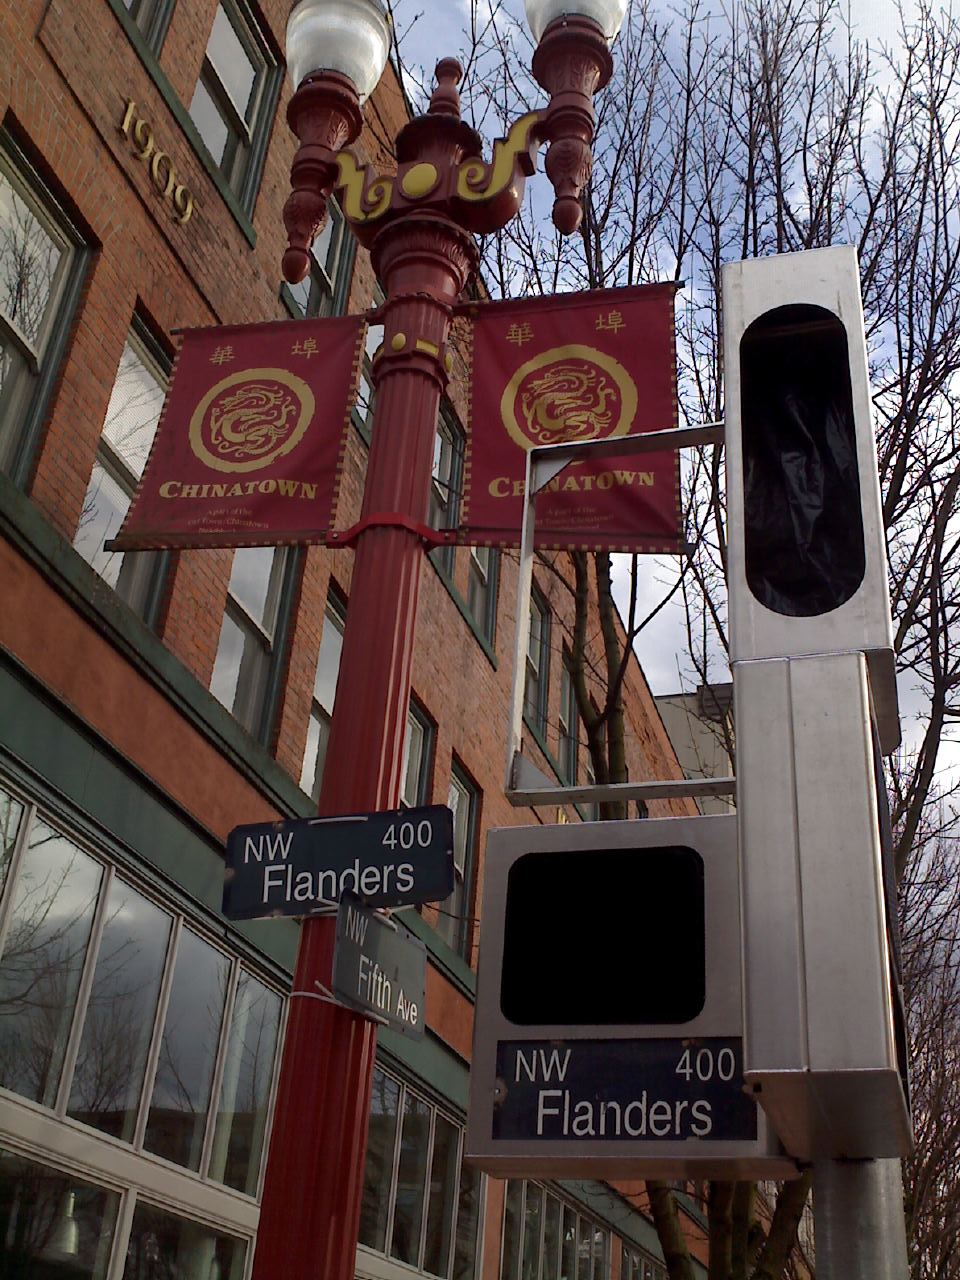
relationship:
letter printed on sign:
[532, 1085, 565, 1135] [486, 1040, 760, 1142]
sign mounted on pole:
[486, 1040, 760, 1142] [804, 1148, 908, 1275]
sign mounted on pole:
[328, 883, 430, 1041] [246, 209, 483, 1277]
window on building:
[72, 437, 145, 597] [2, 7, 749, 1277]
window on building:
[197, 594, 287, 733] [9, 7, 836, 1277]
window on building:
[208, 534, 302, 635] [9, 7, 836, 1277]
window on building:
[274, 695, 336, 796] [9, 7, 836, 1277]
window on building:
[382, 698, 437, 809] [2, 7, 749, 1277]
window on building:
[456, 566, 511, 646] [9, 7, 836, 1277]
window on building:
[100, 904, 318, 1211] [51, 48, 536, 891]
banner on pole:
[485, 288, 663, 528] [346, 235, 520, 1121]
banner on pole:
[54, 288, 375, 612] [278, 116, 518, 836]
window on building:
[164, 916, 249, 1204] [37, 22, 569, 969]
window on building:
[354, 1043, 487, 1276] [53, 54, 536, 1048]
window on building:
[213, 532, 415, 842] [47, 123, 638, 1264]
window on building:
[363, 1017, 516, 1270] [40, 104, 537, 1006]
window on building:
[400, 1106, 602, 1266] [53, 54, 536, 1048]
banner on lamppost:
[460, 281, 684, 555] [241, 50, 481, 1280]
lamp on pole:
[744, 705, 862, 1059] [520, 713, 732, 1159]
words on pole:
[491, 994, 808, 1233] [430, 610, 840, 1213]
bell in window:
[51, 1171, 112, 1268] [5, 1134, 174, 1270]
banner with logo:
[460, 281, 684, 555] [489, 279, 635, 495]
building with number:
[2, 7, 749, 1277] [104, 87, 203, 235]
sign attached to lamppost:
[222, 805, 452, 922] [241, 50, 481, 1280]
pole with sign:
[456, 230, 930, 1275] [492, 1038, 758, 1142]